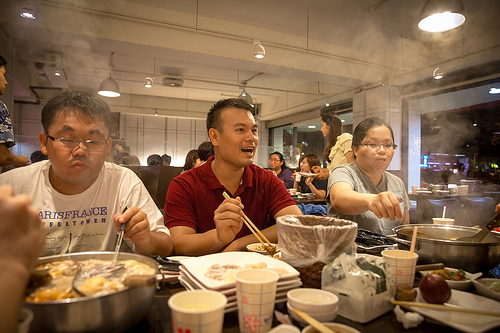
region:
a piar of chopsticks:
[221, 185, 276, 252]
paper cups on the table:
[167, 260, 282, 332]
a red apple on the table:
[417, 267, 455, 307]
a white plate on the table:
[387, 271, 496, 327]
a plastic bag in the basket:
[269, 205, 366, 290]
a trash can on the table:
[274, 209, 359, 291]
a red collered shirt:
[160, 155, 303, 247]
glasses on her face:
[356, 136, 402, 156]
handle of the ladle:
[122, 269, 157, 295]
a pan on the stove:
[383, 215, 498, 272]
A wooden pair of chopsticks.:
[216, 192, 283, 254]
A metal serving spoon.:
[102, 199, 132, 277]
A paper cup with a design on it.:
[225, 271, 276, 331]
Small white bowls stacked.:
[286, 287, 350, 322]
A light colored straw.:
[407, 224, 419, 260]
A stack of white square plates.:
[165, 247, 305, 312]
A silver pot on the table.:
[389, 214, 499, 273]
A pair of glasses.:
[34, 124, 121, 154]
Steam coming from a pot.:
[330, 22, 497, 273]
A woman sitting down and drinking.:
[292, 156, 319, 198]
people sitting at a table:
[0, 76, 426, 295]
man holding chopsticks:
[191, 95, 288, 261]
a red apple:
[421, 269, 453, 311]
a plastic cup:
[236, 268, 286, 331]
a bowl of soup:
[11, 245, 175, 322]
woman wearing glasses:
[356, 134, 401, 159]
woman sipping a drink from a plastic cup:
[291, 153, 326, 205]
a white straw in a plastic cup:
[436, 198, 453, 224]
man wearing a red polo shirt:
[158, 160, 294, 244]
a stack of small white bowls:
[287, 283, 343, 322]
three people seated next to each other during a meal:
[0, 82, 419, 257]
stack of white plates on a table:
[175, 244, 305, 314]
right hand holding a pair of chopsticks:
[211, 187, 276, 249]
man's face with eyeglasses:
[31, 85, 122, 190]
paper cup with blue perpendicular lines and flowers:
[231, 265, 281, 332]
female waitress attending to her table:
[301, 109, 357, 184]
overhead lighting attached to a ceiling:
[91, 42, 326, 104]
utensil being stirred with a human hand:
[457, 196, 499, 256]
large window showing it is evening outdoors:
[398, 92, 498, 192]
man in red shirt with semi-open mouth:
[158, 94, 300, 252]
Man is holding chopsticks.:
[166, 89, 293, 251]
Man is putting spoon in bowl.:
[3, 87, 173, 327]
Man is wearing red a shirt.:
[163, 95, 304, 252]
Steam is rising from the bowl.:
[396, 82, 498, 275]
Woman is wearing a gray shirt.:
[323, 119, 417, 235]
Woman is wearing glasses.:
[326, 116, 412, 231]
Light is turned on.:
[403, 0, 473, 42]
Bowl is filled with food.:
[26, 248, 159, 331]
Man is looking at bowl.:
[1, 88, 173, 250]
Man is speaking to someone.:
[163, 95, 304, 257]